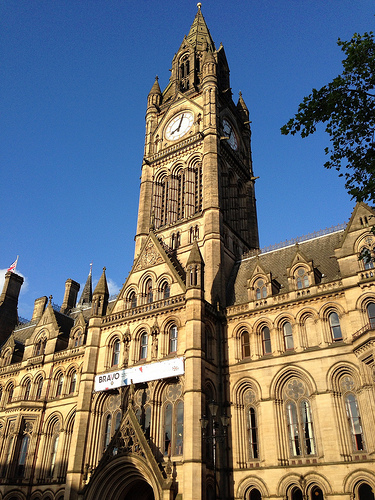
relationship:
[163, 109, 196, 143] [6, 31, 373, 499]
clock on building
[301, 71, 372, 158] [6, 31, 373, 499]
tree next to building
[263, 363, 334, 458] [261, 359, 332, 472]
curtains in window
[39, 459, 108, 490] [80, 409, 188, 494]
shadows on entrance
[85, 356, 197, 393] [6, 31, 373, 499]
sign on building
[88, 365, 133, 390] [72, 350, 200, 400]
letters on sign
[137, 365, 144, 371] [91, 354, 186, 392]
triangles on sign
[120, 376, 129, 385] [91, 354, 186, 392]
triangles on sign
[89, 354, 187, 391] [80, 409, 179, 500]
banner hanging over entrance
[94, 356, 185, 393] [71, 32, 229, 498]
banner hanging over building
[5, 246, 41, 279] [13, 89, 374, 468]
flag on building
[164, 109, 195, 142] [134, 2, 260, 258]
clock on tower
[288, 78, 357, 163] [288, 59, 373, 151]
branches with leaves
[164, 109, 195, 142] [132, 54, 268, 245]
clock clock on tower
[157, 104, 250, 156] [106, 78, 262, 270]
face in tower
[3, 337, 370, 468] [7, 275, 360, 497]
windows in buildings